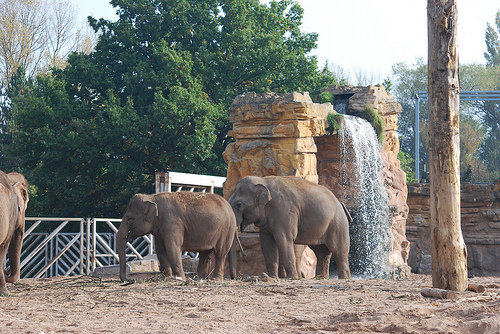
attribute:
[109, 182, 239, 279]
elephant — baby, in the middle, gre, grey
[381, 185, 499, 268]
wall — stoe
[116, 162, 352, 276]
elephants — standing still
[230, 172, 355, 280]
elephant — grey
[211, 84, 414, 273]
structure — brown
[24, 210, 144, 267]
fencing — silver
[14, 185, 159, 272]
doors — white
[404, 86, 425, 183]
pole — gre